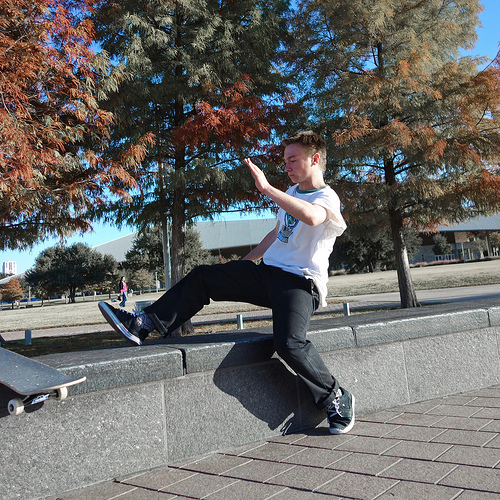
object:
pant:
[144, 257, 340, 414]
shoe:
[325, 385, 358, 437]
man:
[98, 128, 360, 438]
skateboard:
[0, 342, 91, 414]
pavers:
[376, 443, 467, 482]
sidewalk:
[147, 306, 499, 382]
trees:
[335, 2, 497, 307]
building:
[1, 258, 17, 280]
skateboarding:
[0, 340, 86, 416]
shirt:
[257, 185, 347, 304]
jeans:
[139, 259, 335, 405]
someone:
[118, 271, 130, 306]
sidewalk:
[1, 276, 499, 338]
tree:
[112, 1, 293, 336]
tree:
[2, 2, 145, 250]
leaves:
[195, 33, 213, 49]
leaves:
[393, 65, 413, 82]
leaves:
[39, 17, 56, 34]